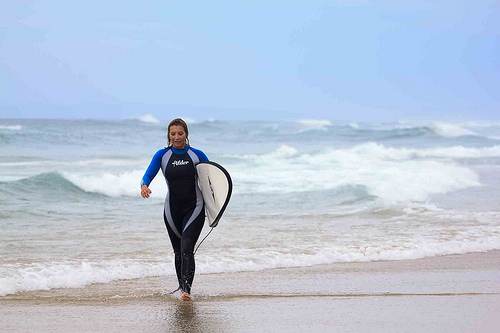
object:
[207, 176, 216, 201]
logo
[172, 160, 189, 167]
print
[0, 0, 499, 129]
sky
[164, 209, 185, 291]
legs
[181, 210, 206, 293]
legs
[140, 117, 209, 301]
woman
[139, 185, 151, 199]
hand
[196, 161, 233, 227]
surfboard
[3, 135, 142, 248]
waves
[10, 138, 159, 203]
water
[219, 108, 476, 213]
waves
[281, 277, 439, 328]
sand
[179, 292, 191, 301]
feet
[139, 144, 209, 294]
top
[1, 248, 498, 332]
beach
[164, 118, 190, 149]
hair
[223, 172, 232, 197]
edge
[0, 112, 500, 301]
ocean